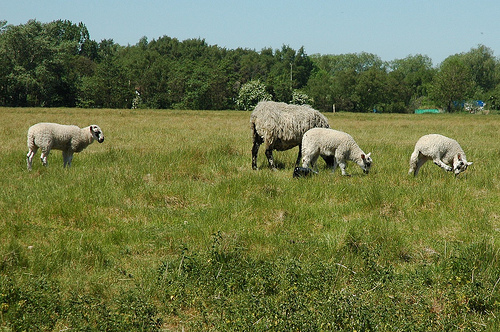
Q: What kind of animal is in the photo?
A: Sheep.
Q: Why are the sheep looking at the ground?
A: They are eating.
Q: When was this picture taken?
A: The afternoon.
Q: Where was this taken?
A: A field.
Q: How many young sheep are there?
A: Three.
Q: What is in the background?
A: Trees.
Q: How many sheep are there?
A: Four.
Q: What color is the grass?
A: Green.